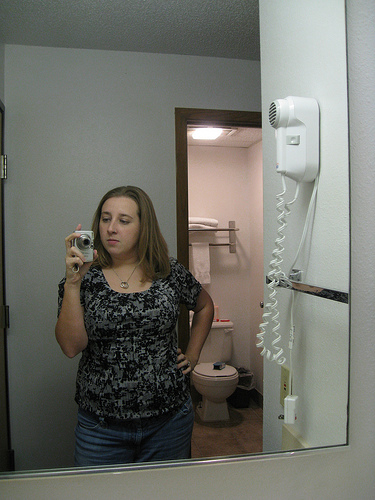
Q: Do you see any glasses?
A: No, there are no glasses.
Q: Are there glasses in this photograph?
A: No, there are no glasses.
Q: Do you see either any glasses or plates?
A: No, there are no glasses or plates.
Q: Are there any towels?
A: Yes, there is a towel.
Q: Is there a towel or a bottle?
A: Yes, there is a towel.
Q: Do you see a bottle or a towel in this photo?
A: Yes, there is a towel.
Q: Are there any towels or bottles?
A: Yes, there is a towel.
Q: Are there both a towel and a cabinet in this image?
A: No, there is a towel but no cabinets.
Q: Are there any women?
A: Yes, there is a woman.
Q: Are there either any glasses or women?
A: Yes, there is a woman.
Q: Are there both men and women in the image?
A: No, there is a woman but no men.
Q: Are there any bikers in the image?
A: No, there are no bikers.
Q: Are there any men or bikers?
A: No, there are no bikers or men.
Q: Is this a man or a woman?
A: This is a woman.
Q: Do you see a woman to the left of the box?
A: Yes, there is a woman to the left of the box.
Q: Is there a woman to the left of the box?
A: Yes, there is a woman to the left of the box.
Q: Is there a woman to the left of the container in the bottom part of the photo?
A: Yes, there is a woman to the left of the box.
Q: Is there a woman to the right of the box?
A: No, the woman is to the left of the box.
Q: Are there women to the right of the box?
A: No, the woman is to the left of the box.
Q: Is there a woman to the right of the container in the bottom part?
A: No, the woman is to the left of the box.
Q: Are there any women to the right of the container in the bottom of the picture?
A: No, the woman is to the left of the box.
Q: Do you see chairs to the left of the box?
A: No, there is a woman to the left of the box.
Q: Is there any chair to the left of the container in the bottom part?
A: No, there is a woman to the left of the box.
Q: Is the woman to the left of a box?
A: Yes, the woman is to the left of a box.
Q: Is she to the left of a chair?
A: No, the woman is to the left of a box.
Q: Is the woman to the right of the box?
A: No, the woman is to the left of the box.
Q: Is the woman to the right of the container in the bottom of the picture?
A: No, the woman is to the left of the box.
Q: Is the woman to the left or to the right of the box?
A: The woman is to the left of the box.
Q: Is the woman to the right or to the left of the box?
A: The woman is to the left of the box.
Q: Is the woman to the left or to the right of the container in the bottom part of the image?
A: The woman is to the left of the box.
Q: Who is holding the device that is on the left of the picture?
A: The woman is holding the camera.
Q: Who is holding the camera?
A: The woman is holding the camera.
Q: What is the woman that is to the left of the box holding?
A: The woman is holding the camera.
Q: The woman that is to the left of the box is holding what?
A: The woman is holding the camera.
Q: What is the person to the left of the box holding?
A: The woman is holding the camera.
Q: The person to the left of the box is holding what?
A: The woman is holding the camera.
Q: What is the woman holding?
A: The woman is holding the camera.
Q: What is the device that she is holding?
A: The device is a camera.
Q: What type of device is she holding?
A: The woman is holding the camera.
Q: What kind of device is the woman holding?
A: The woman is holding the camera.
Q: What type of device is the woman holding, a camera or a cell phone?
A: The woman is holding a camera.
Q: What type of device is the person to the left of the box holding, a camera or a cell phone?
A: The woman is holding a camera.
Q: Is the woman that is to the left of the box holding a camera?
A: Yes, the woman is holding a camera.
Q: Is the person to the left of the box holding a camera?
A: Yes, the woman is holding a camera.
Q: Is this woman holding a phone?
A: No, the woman is holding a camera.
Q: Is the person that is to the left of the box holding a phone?
A: No, the woman is holding a camera.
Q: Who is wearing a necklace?
A: The woman is wearing a necklace.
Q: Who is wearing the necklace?
A: The woman is wearing a necklace.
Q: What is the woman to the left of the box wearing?
A: The woman is wearing a necklace.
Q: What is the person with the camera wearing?
A: The woman is wearing a necklace.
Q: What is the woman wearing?
A: The woman is wearing a necklace.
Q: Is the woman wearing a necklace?
A: Yes, the woman is wearing a necklace.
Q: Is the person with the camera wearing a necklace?
A: Yes, the woman is wearing a necklace.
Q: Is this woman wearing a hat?
A: No, the woman is wearing a necklace.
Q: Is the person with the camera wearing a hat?
A: No, the woman is wearing a necklace.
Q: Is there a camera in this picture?
A: Yes, there is a camera.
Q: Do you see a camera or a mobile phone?
A: Yes, there is a camera.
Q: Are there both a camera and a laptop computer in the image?
A: No, there is a camera but no laptops.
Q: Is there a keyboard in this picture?
A: No, there are no keyboards.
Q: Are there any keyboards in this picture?
A: No, there are no keyboards.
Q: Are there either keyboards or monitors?
A: No, there are no keyboards or monitors.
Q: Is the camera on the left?
A: Yes, the camera is on the left of the image.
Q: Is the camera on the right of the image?
A: No, the camera is on the left of the image.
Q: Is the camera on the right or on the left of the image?
A: The camera is on the left of the image.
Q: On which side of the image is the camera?
A: The camera is on the left of the image.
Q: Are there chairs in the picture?
A: No, there are no chairs.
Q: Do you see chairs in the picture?
A: No, there are no chairs.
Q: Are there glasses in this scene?
A: No, there are no glasses.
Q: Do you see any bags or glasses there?
A: No, there are no glasses or bags.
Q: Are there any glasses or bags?
A: No, there are no glasses or bags.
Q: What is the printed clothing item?
A: The clothing item is a blouse.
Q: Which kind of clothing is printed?
A: The clothing is a blouse.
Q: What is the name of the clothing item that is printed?
A: The clothing item is a blouse.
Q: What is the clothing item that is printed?
A: The clothing item is a blouse.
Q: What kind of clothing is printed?
A: The clothing is a blouse.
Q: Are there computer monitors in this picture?
A: No, there are no computer monitors.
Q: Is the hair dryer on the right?
A: Yes, the hair dryer is on the right of the image.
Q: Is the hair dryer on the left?
A: No, the hair dryer is on the right of the image.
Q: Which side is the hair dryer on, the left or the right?
A: The hair dryer is on the right of the image.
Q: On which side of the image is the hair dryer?
A: The hair dryer is on the right of the image.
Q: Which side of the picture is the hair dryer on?
A: The hair dryer is on the right of the image.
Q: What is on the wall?
A: The hair dryer is on the wall.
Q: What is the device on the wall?
A: The device is a hair dryer.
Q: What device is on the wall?
A: The device is a hair dryer.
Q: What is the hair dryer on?
A: The hair dryer is on the wall.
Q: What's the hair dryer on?
A: The hair dryer is on the wall.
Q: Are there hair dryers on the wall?
A: Yes, there is a hair dryer on the wall.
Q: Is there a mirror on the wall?
A: No, there is a hair dryer on the wall.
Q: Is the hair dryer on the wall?
A: Yes, the hair dryer is on the wall.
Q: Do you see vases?
A: No, there are no vases.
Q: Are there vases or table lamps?
A: No, there are no vases or table lamps.